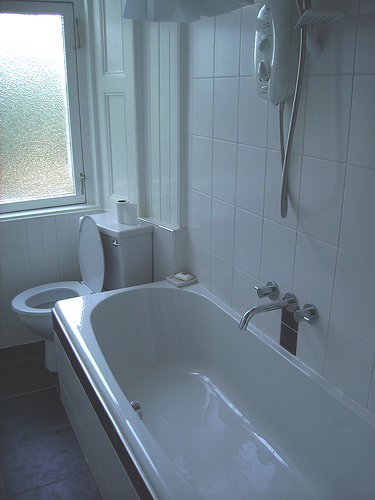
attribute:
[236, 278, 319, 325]
faucet — silver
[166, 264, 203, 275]
soap — dish, white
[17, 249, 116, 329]
toilet — porcelain, white, clean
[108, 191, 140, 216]
paper — back, toilet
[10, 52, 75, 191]
window — translucent, bright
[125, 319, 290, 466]
bathtub — porcelain, large, spotless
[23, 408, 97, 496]
tiles — gray, black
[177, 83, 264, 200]
walls — white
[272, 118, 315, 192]
hose — silver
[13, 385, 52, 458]
tile — black, gray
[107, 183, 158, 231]
roll — empty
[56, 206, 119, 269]
seat — up, open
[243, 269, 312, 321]
knobs — cold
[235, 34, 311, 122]
shower — attached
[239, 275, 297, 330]
tub — deep, big, chrome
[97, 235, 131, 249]
handle — flushing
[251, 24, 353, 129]
head — flexible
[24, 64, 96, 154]
glass — frosted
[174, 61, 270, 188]
wall — white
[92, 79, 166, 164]
wood — white